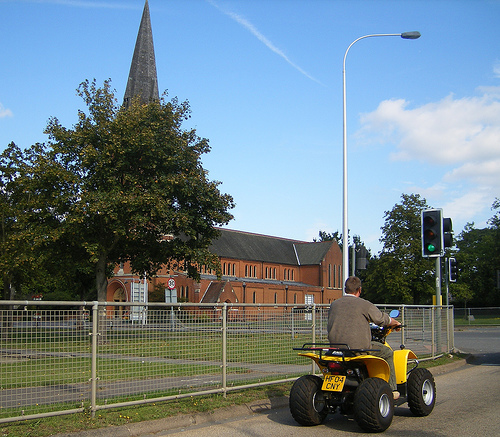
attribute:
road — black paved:
[465, 370, 484, 381]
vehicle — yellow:
[276, 279, 444, 428]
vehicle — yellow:
[255, 283, 455, 419]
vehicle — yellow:
[260, 274, 449, 428]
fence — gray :
[9, 282, 289, 418]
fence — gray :
[7, 277, 462, 414]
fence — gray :
[9, 284, 463, 429]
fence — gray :
[11, 285, 461, 401]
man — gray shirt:
[324, 267, 397, 352]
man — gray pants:
[337, 350, 399, 400]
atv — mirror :
[376, 301, 411, 335]